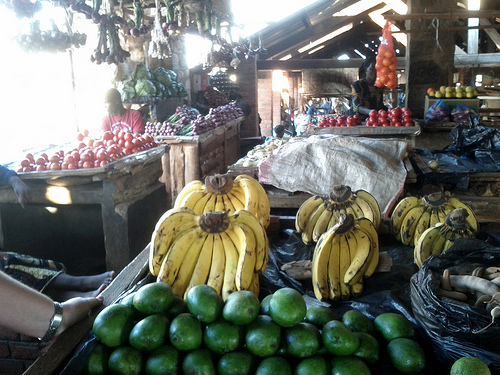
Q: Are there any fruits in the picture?
A: Yes, there is a fruit.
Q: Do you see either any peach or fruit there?
A: Yes, there is a fruit.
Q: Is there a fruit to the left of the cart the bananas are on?
A: Yes, there is a fruit to the left of the cart.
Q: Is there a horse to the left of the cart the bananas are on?
A: No, there is a fruit to the left of the cart.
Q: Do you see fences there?
A: No, there are no fences.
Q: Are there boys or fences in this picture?
A: No, there are no fences or boys.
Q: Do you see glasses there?
A: No, there are no glasses.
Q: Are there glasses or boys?
A: No, there are no glasses or boys.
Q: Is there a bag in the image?
A: Yes, there is a bag.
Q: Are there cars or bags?
A: Yes, there is a bag.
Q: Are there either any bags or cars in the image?
A: Yes, there is a bag.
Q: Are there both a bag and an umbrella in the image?
A: No, there is a bag but no umbrellas.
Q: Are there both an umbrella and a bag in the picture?
A: No, there is a bag but no umbrellas.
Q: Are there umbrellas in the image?
A: No, there are no umbrellas.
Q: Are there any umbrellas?
A: No, there are no umbrellas.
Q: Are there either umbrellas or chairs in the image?
A: No, there are no umbrellas or chairs.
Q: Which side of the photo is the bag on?
A: The bag is on the right of the image.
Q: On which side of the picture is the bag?
A: The bag is on the right of the image.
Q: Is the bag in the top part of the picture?
A: Yes, the bag is in the top of the image.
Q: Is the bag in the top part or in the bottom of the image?
A: The bag is in the top of the image.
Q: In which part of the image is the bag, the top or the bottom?
A: The bag is in the top of the image.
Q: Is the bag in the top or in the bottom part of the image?
A: The bag is in the top of the image.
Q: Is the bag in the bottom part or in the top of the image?
A: The bag is in the top of the image.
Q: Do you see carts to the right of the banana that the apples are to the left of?
A: Yes, there is a cart to the right of the banana.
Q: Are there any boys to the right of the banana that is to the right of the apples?
A: No, there is a cart to the right of the banana.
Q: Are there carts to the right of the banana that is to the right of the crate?
A: Yes, there is a cart to the right of the banana.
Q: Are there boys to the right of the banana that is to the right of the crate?
A: No, there is a cart to the right of the banana.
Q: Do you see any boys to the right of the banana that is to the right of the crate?
A: No, there is a cart to the right of the banana.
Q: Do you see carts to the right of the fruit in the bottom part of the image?
A: Yes, there is a cart to the right of the fruit.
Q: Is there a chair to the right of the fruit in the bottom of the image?
A: No, there is a cart to the right of the fruit.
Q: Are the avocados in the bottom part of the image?
A: Yes, the avocados are in the bottom of the image.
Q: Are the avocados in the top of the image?
A: No, the avocados are in the bottom of the image.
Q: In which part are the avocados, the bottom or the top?
A: The avocados are in the bottom of the image.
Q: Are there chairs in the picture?
A: No, there are no chairs.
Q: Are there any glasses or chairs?
A: No, there are no chairs or glasses.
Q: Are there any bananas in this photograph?
A: Yes, there are bananas.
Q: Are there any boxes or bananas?
A: Yes, there are bananas.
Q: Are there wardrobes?
A: No, there are no wardrobes.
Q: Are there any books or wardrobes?
A: No, there are no wardrobes or books.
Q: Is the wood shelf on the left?
A: Yes, the shelf is on the left of the image.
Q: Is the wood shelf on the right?
A: No, the shelf is on the left of the image.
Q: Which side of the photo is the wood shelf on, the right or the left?
A: The shelf is on the left of the image.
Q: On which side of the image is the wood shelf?
A: The shelf is on the left of the image.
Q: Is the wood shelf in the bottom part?
A: Yes, the shelf is in the bottom of the image.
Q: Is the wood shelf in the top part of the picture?
A: No, the shelf is in the bottom of the image.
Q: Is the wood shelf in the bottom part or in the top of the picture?
A: The shelf is in the bottom of the image.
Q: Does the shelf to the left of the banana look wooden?
A: Yes, the shelf is wooden.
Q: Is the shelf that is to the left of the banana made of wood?
A: Yes, the shelf is made of wood.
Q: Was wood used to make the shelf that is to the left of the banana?
A: Yes, the shelf is made of wood.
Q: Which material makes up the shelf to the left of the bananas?
A: The shelf is made of wood.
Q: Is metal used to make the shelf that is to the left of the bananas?
A: No, the shelf is made of wood.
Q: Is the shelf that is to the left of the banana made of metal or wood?
A: The shelf is made of wood.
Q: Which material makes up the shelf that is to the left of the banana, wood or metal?
A: The shelf is made of wood.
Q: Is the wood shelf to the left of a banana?
A: Yes, the shelf is to the left of a banana.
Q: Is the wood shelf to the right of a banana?
A: No, the shelf is to the left of a banana.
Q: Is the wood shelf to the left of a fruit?
A: Yes, the shelf is to the left of a fruit.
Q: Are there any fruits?
A: Yes, there is a fruit.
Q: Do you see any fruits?
A: Yes, there is a fruit.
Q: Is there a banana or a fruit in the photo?
A: Yes, there is a fruit.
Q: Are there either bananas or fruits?
A: Yes, there is a fruit.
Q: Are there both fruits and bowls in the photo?
A: No, there is a fruit but no bowls.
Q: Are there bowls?
A: No, there are no bowls.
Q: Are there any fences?
A: No, there are no fences.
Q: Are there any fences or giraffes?
A: No, there are no fences or giraffes.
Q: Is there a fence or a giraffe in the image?
A: No, there are no fences or giraffes.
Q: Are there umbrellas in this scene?
A: No, there are no umbrellas.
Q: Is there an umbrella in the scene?
A: No, there are no umbrellas.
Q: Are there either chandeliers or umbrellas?
A: No, there are no umbrellas or chandeliers.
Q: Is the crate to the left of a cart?
A: Yes, the crate is to the left of a cart.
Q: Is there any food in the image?
A: Yes, there is food.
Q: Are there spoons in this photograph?
A: No, there are no spoons.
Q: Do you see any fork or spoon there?
A: No, there are no spoons or forks.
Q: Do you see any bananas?
A: Yes, there is a banana.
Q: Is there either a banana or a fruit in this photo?
A: Yes, there is a banana.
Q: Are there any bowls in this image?
A: No, there are no bowls.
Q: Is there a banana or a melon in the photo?
A: Yes, there is a banana.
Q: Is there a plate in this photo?
A: No, there are no plates.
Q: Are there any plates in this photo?
A: No, there are no plates.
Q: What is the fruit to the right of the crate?
A: The fruit is a banana.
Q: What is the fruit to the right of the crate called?
A: The fruit is a banana.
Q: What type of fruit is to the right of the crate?
A: The fruit is a banana.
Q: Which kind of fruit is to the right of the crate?
A: The fruit is a banana.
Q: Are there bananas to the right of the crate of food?
A: Yes, there is a banana to the right of the crate.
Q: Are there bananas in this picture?
A: Yes, there is a banana.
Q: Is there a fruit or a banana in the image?
A: Yes, there is a banana.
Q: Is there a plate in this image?
A: No, there are no plates.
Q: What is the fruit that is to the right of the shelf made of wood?
A: The fruit is a banana.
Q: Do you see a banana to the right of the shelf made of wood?
A: Yes, there is a banana to the right of the shelf.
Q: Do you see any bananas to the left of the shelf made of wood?
A: No, the banana is to the right of the shelf.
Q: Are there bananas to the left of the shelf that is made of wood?
A: No, the banana is to the right of the shelf.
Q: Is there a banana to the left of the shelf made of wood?
A: No, the banana is to the right of the shelf.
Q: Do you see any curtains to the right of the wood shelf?
A: No, there is a banana to the right of the shelf.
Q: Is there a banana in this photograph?
A: Yes, there is a banana.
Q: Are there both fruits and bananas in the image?
A: Yes, there are both a banana and a fruit.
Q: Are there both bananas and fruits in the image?
A: Yes, there are both a banana and a fruit.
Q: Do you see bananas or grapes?
A: Yes, there is a banana.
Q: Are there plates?
A: No, there are no plates.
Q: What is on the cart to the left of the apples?
A: The banana is on the cart.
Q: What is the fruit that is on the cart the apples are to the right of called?
A: The fruit is a banana.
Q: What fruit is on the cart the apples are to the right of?
A: The fruit is a banana.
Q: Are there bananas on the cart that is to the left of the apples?
A: Yes, there is a banana on the cart.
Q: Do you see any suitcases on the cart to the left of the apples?
A: No, there is a banana on the cart.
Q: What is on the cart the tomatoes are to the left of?
A: The banana is on the cart.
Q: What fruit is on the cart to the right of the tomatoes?
A: The fruit is a banana.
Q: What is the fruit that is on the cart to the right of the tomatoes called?
A: The fruit is a banana.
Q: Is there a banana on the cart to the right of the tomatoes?
A: Yes, there is a banana on the cart.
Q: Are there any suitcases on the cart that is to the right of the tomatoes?
A: No, there is a banana on the cart.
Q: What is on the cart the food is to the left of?
A: The banana is on the cart.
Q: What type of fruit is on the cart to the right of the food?
A: The fruit is a banana.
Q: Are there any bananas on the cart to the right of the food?
A: Yes, there is a banana on the cart.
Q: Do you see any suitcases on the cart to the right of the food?
A: No, there is a banana on the cart.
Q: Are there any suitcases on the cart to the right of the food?
A: No, there is a banana on the cart.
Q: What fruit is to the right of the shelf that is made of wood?
A: The fruit is a banana.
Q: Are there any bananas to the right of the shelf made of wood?
A: Yes, there is a banana to the right of the shelf.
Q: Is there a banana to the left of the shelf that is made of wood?
A: No, the banana is to the right of the shelf.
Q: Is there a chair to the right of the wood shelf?
A: No, there is a banana to the right of the shelf.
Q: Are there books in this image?
A: No, there are no books.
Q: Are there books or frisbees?
A: No, there are no books or frisbees.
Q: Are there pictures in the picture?
A: No, there are no pictures.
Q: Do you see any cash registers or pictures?
A: No, there are no pictures or cash registers.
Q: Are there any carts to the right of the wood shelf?
A: Yes, there is a cart to the right of the shelf.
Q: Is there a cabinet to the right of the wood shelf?
A: No, there is a cart to the right of the shelf.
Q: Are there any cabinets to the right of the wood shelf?
A: No, there is a cart to the right of the shelf.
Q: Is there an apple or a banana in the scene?
A: Yes, there is a banana.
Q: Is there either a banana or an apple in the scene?
A: Yes, there is a banana.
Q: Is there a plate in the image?
A: No, there are no plates.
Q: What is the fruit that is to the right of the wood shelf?
A: The fruit is a banana.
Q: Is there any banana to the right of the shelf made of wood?
A: Yes, there is a banana to the right of the shelf.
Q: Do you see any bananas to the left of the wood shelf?
A: No, the banana is to the right of the shelf.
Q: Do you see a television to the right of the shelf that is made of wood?
A: No, there is a banana to the right of the shelf.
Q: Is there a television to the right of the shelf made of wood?
A: No, there is a banana to the right of the shelf.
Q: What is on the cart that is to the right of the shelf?
A: The banana is on the cart.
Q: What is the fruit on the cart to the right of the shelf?
A: The fruit is a banana.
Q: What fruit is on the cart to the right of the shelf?
A: The fruit is a banana.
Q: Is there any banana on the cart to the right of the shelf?
A: Yes, there is a banana on the cart.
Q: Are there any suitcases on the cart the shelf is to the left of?
A: No, there is a banana on the cart.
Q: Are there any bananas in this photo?
A: Yes, there are bananas.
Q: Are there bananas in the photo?
A: Yes, there are bananas.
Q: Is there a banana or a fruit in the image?
A: Yes, there are bananas.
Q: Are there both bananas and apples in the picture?
A: Yes, there are both bananas and an apple.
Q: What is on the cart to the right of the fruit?
A: The bananas are on the cart.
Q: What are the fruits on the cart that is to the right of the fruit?
A: The fruits are bananas.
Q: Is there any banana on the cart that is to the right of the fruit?
A: Yes, there are bananas on the cart.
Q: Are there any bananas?
A: Yes, there are bananas.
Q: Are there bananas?
A: Yes, there are bananas.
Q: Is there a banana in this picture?
A: Yes, there are bananas.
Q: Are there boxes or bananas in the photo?
A: Yes, there are bananas.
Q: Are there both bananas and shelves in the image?
A: Yes, there are both bananas and a shelf.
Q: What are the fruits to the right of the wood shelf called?
A: The fruits are bananas.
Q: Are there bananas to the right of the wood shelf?
A: Yes, there are bananas to the right of the shelf.